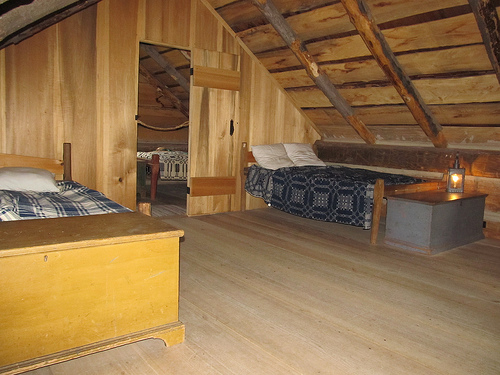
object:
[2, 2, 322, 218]
walls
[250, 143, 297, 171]
pillow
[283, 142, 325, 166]
pillow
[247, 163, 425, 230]
blanket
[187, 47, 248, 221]
door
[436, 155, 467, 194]
lantern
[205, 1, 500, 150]
ceiling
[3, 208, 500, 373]
floor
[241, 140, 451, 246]
frame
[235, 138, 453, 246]
bed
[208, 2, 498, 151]
rafters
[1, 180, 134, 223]
blanket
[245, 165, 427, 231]
comforter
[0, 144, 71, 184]
frame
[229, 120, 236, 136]
handle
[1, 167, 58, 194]
pillow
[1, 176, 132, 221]
comforter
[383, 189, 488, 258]
box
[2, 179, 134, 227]
bedspread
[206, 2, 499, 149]
roof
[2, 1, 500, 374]
bedroom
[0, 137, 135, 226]
bed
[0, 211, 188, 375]
chest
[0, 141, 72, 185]
head board